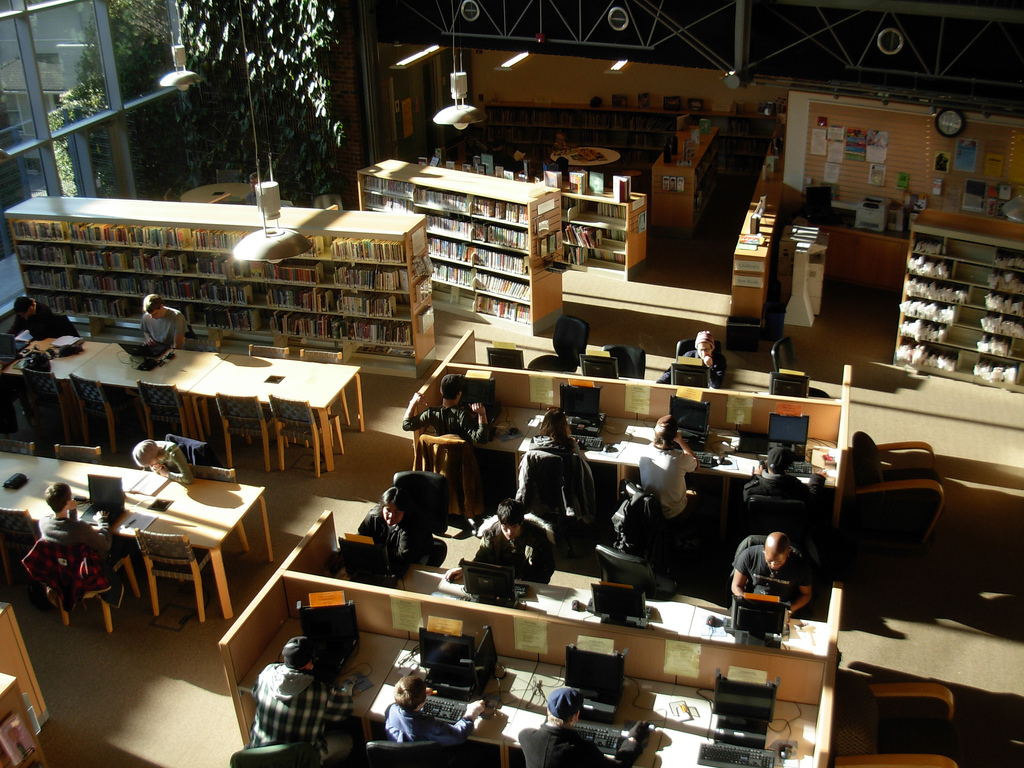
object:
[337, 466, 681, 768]
indoors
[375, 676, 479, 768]
man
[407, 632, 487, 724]
computer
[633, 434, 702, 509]
man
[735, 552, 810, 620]
shirt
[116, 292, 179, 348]
man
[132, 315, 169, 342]
shirt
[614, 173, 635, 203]
book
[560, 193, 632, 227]
bookshelf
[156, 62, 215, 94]
light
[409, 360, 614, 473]
table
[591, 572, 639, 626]
monitor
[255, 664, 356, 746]
jacket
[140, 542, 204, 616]
chair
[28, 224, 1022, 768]
library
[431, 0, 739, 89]
ceiling fixture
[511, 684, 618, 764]
man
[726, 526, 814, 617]
person